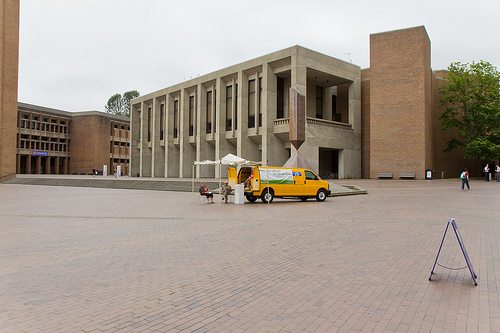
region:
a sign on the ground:
[421, 209, 490, 296]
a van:
[293, 162, 327, 205]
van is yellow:
[300, 162, 326, 192]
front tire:
[315, 187, 330, 204]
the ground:
[56, 228, 329, 323]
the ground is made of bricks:
[87, 220, 310, 324]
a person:
[457, 165, 473, 188]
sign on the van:
[259, 168, 297, 185]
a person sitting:
[200, 178, 217, 206]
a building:
[136, 83, 293, 148]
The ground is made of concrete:
[72, 215, 290, 309]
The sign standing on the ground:
[421, 210, 486, 295]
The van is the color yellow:
[184, 138, 346, 215]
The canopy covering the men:
[187, 143, 274, 207]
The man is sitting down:
[191, 175, 217, 202]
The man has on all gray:
[218, 175, 237, 206]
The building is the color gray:
[122, 90, 300, 160]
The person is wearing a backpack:
[453, 158, 475, 191]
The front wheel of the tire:
[313, 184, 330, 202]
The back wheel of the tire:
[258, 186, 276, 204]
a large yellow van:
[230, 163, 332, 202]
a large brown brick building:
[370, 23, 434, 183]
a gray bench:
[397, 168, 420, 179]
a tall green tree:
[436, 62, 498, 171]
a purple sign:
[424, 214, 484, 290]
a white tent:
[193, 150, 272, 206]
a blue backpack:
[458, 169, 467, 181]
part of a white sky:
[31, 0, 257, 40]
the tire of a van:
[316, 188, 327, 202]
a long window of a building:
[248, 77, 256, 128]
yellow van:
[227, 162, 326, 202]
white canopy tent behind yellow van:
[189, 149, 259, 204]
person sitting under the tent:
[197, 176, 213, 202]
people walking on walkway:
[456, 162, 494, 190]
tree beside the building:
[436, 54, 498, 171]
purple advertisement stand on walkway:
[423, 214, 485, 288]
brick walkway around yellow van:
[13, 174, 493, 323]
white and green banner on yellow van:
[258, 167, 293, 184]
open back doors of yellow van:
[228, 163, 260, 193]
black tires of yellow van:
[245, 194, 326, 201]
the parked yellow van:
[227, 167, 332, 202]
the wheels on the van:
[244, 188, 326, 203]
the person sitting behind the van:
[198, 180, 214, 205]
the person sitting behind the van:
[220, 180, 232, 203]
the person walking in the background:
[460, 167, 472, 190]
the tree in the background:
[435, 59, 499, 174]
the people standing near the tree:
[482, 162, 498, 182]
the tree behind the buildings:
[104, 89, 138, 117]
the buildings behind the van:
[0, 0, 499, 182]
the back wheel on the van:
[261, 189, 272, 202]